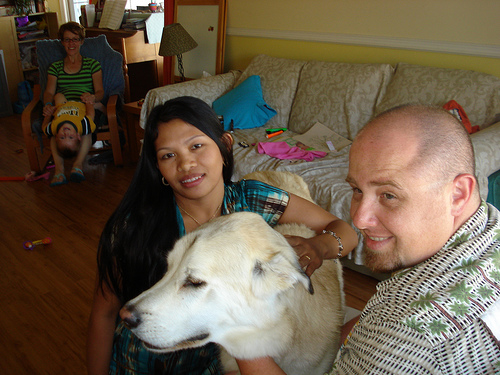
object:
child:
[37, 89, 102, 149]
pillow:
[213, 75, 276, 134]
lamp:
[158, 23, 200, 82]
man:
[237, 102, 499, 373]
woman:
[85, 95, 359, 374]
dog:
[118, 170, 345, 373]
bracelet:
[313, 228, 343, 259]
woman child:
[40, 20, 106, 187]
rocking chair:
[23, 32, 127, 176]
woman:
[43, 20, 105, 188]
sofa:
[137, 54, 499, 282]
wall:
[224, 0, 498, 82]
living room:
[0, 0, 499, 373]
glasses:
[58, 34, 81, 45]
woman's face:
[62, 31, 82, 56]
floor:
[0, 103, 141, 373]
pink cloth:
[257, 141, 329, 162]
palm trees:
[453, 253, 500, 291]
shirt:
[43, 99, 98, 139]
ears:
[250, 250, 315, 296]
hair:
[91, 95, 236, 302]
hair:
[353, 100, 481, 206]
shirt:
[326, 197, 499, 374]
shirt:
[45, 55, 103, 103]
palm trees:
[409, 287, 464, 331]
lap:
[43, 100, 100, 146]